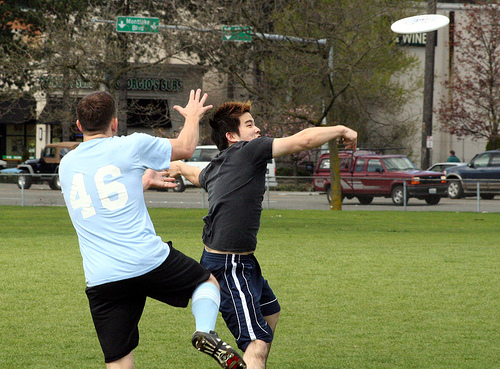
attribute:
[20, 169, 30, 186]
tire — black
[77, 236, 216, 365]
shorts — black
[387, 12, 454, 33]
frisbee —  white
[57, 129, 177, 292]
shirt — blue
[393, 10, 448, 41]
frisbee — white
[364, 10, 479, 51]
frisbee — white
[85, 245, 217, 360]
shorts — black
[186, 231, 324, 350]
shorts — blue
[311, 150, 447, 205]
truck — red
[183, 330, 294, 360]
wearing cleats —  man's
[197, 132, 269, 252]
shirt — black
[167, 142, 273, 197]
van —  white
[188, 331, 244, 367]
cleat —  black/white/red 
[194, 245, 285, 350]
shorts — blue, white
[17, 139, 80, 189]
jeep —  black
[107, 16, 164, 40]
sign — green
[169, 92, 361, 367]
man —  asian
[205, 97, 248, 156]
hair —  multi-colored 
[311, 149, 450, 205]
pick-up truck —  red ,  pick-up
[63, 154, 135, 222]
shirt number/46 — 46, shirt 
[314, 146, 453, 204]
pick up — red, with top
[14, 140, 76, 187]
jeep — blue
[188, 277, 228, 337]
shin sock — light blue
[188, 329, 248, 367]
cleat — worn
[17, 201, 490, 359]
grass — above 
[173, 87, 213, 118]
mans hand —  man's,  ''high-five''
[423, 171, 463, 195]
light — clear, orange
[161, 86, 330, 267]
shirt — black